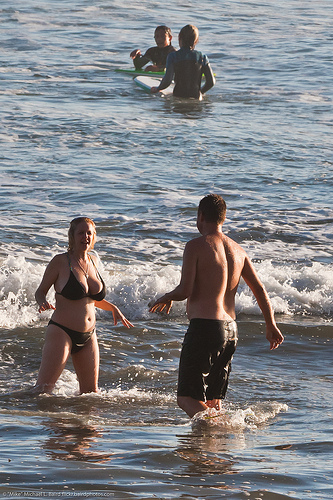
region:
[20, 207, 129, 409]
woman in black bikini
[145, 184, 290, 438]
man in black swim trunks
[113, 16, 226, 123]
people in water with surfboard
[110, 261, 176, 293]
white foam of waves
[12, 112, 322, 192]
water in the ocean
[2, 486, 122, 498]
copyright of a photographer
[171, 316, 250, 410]
swim trunks on a man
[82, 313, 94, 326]
belly button of a woman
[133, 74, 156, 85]
surfboard in the water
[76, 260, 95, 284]
necklace on a woman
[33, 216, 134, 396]
a woman wearing a bikini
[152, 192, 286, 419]
a man wearing black shorts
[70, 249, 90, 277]
a necklace on a woman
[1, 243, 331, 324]
white waves on the water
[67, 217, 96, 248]
wet hair on a woman's head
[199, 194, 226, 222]
short brown hair on a man's head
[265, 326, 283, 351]
a man's right hand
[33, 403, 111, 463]
the reflection of a woman on water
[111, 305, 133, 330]
a woman's left hand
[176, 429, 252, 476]
the reflection of a man on water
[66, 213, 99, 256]
the head of a woman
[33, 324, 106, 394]
the legs of a woman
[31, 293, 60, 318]
the hand of the woman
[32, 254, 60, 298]
the arm of the woman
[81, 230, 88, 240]
the nose of the woman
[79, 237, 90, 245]
the mouth of the woman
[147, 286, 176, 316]
the hand of the man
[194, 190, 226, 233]
the head of the man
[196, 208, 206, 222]
the ear of the man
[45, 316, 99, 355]
a black bikini bottom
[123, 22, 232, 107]
two people surfing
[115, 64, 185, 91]
surf boards floating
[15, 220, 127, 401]
woman enjoying the beach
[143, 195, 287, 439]
man enjoying the beach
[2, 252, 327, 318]
waves crashing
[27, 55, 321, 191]
calm waters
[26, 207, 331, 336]
beach goers enjoying the water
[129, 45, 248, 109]
two girls in surf suits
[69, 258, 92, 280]
jewelry being exposed to the ocean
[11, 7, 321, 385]
four people enjoying the sea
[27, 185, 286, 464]
two people playing in the surf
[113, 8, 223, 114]
Two surfers waiting for a wave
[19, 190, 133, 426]
Woman in a bikini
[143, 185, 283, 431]
Man walking into the ocean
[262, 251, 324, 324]
Ocean wave breaking on the beach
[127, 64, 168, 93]
White Surfboard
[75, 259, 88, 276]
Necklace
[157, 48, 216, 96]
black and blue wetsuit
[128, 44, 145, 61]
wrist band attached to surfboard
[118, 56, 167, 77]
green surfboard